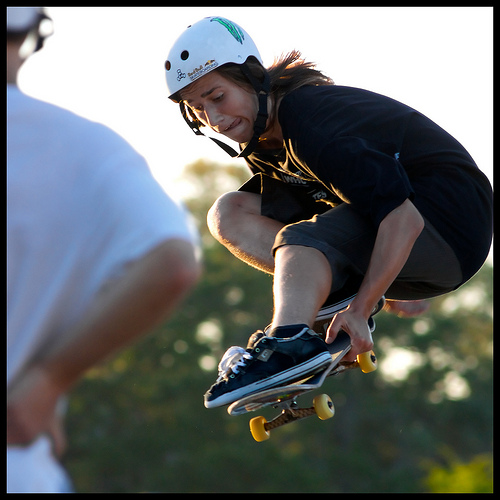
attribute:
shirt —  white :
[8, 82, 195, 499]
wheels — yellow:
[304, 392, 339, 416]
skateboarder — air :
[145, 18, 485, 435]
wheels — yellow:
[240, 363, 404, 450]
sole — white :
[208, 362, 337, 394]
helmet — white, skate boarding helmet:
[164, 16, 270, 162]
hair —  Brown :
[226, 52, 332, 83]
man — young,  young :
[170, 15, 494, 405]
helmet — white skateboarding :
[130, 15, 285, 122]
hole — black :
[177, 47, 190, 63]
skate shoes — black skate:
[161, 319, 373, 398]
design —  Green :
[212, 19, 249, 44]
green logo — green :
[203, 15, 250, 46]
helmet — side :
[141, 9, 269, 108]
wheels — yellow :
[248, 349, 378, 442]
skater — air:
[146, 20, 495, 442]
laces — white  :
[216, 345, 254, 377]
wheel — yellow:
[357, 349, 377, 373]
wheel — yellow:
[249, 414, 269, 439]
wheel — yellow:
[312, 391, 334, 418]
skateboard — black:
[226, 297, 380, 442]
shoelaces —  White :
[211, 336, 253, 371]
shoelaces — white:
[212, 307, 297, 374]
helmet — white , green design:
[136, 39, 292, 100]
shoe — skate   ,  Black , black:
[203, 325, 333, 409]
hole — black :
[179, 49, 189, 61]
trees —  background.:
[117, 174, 485, 387]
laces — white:
[212, 332, 253, 381]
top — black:
[272, 83, 483, 218]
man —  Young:
[162, 10, 471, 409]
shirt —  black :
[215, 70, 484, 275]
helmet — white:
[163, 10, 269, 105]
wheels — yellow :
[220, 350, 377, 447]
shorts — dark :
[230, 158, 483, 313]